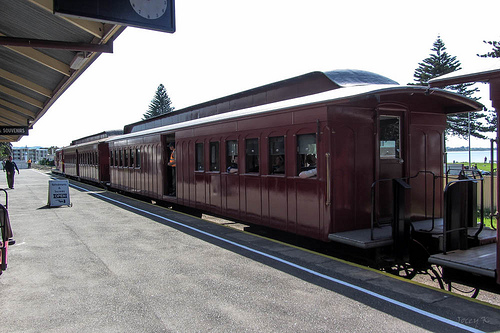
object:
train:
[51, 58, 500, 301]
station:
[0, 0, 500, 333]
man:
[168, 142, 177, 197]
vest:
[167, 151, 176, 167]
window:
[296, 132, 317, 179]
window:
[268, 134, 285, 176]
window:
[245, 137, 259, 175]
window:
[226, 139, 238, 173]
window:
[209, 142, 220, 172]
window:
[194, 142, 205, 173]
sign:
[47, 178, 72, 208]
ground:
[0, 168, 435, 332]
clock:
[53, 0, 175, 34]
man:
[3, 156, 19, 189]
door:
[376, 108, 403, 221]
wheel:
[386, 253, 415, 279]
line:
[51, 172, 500, 312]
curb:
[52, 173, 498, 318]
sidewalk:
[1, 169, 500, 332]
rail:
[369, 171, 485, 240]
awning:
[0, 2, 128, 143]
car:
[107, 69, 485, 263]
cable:
[397, 236, 482, 299]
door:
[159, 134, 178, 196]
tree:
[406, 34, 490, 144]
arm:
[298, 169, 317, 179]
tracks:
[396, 265, 498, 307]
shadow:
[47, 169, 500, 333]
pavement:
[1, 167, 500, 329]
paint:
[44, 173, 500, 332]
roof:
[54, 67, 499, 149]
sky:
[12, 0, 498, 148]